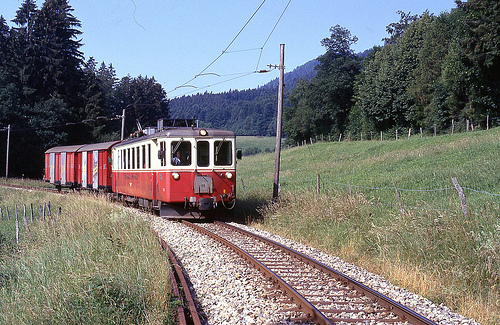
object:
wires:
[165, 0, 268, 95]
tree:
[298, 22, 363, 143]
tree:
[363, 15, 452, 130]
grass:
[0, 188, 167, 324]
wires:
[170, 67, 272, 100]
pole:
[271, 44, 284, 202]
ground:
[0, 139, 500, 325]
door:
[154, 142, 165, 199]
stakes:
[11, 195, 65, 240]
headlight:
[226, 172, 233, 179]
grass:
[234, 128, 500, 322]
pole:
[5, 124, 11, 179]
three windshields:
[171, 140, 232, 166]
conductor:
[172, 151, 182, 165]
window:
[171, 141, 191, 166]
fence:
[287, 114, 489, 148]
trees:
[222, 112, 265, 137]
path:
[167, 214, 467, 324]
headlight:
[172, 172, 180, 180]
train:
[43, 118, 242, 220]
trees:
[423, 2, 496, 130]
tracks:
[6, 172, 435, 322]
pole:
[120, 108, 125, 141]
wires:
[224, 48, 259, 54]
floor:
[0, 128, 499, 323]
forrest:
[1, 0, 499, 322]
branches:
[346, 9, 440, 139]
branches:
[281, 22, 361, 148]